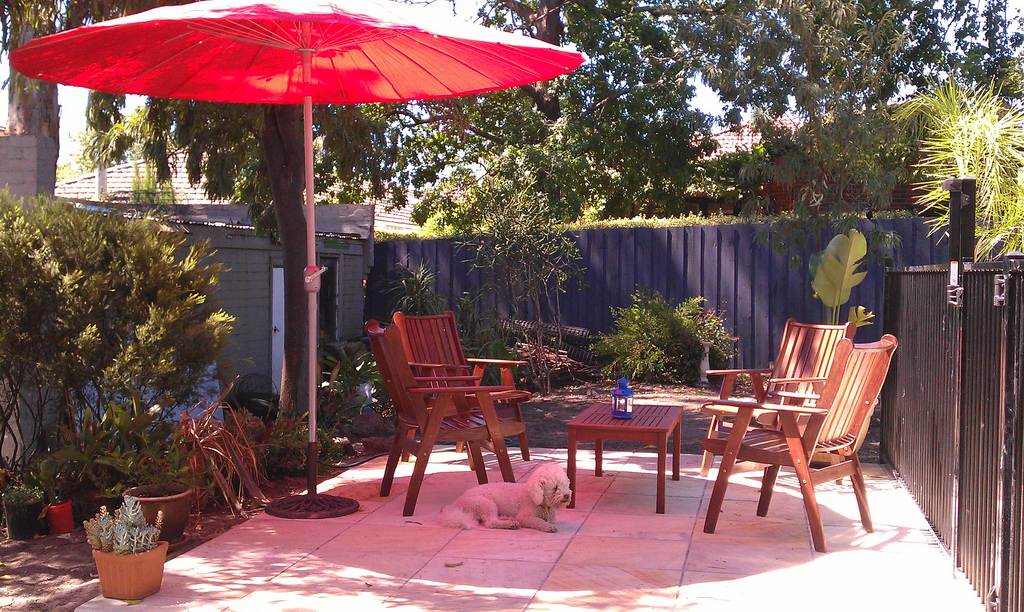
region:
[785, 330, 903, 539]
the chair is brown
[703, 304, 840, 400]
the chair is brown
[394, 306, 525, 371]
the chair is brown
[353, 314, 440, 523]
the chair is brown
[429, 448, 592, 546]
white dog is lying on the floor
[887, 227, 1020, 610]
the fence is color brown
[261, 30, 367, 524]
the shaft is white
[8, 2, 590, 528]
outdoor patio umbrella open on patio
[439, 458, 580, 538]
poodle with puppy cut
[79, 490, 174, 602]
succulent plant in earthenware pot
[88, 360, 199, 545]
potted plant on backyard patio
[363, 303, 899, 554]
set of wooden patio furniture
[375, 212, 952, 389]
black wooden fence bordering yard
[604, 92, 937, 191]
roof of the next door neighbor's house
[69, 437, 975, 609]
tiled patio with marble look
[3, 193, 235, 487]
shrubbery bordering back yard patio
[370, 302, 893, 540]
table and chairs are wood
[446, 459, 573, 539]
dog is laying on the ground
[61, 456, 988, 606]
ground is square bricks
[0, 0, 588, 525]
red umbrella is large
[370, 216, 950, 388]
fence is wooden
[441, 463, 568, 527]
white dog has its head up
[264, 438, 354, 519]
anchor for the umbrella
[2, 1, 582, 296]
umbrella is open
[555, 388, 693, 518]
a table is color brown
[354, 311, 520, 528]
the chair is wod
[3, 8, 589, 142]
the umbrella is open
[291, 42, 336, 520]
shaft holding an umbrella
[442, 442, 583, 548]
the dog is color white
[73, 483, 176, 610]
a pot has plants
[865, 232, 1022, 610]
the fence is color brown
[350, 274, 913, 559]
four chairs around a table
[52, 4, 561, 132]
large open red umbrella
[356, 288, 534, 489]
chair outside on porch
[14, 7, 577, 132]
open red umbrella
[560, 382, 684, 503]
small brown wooden table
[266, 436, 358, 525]
black bottom of umbrella stand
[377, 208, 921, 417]
navy blue yard fence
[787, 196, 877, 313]
large green tree frond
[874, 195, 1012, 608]
black metal fence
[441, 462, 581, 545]
dog next to table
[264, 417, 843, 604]
black umbrella shadow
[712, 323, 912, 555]
empty brown wooden chair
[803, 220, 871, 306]
A leaf on a stem.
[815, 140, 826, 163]
A leaf on a stem.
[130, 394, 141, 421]
A leaf on a stem.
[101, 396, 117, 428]
A leaf on a stem.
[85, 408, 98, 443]
A leaf on a stem.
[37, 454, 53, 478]
A leaf on a stem.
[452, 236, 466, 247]
A leaf on a stem.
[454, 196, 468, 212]
A leaf on a stem.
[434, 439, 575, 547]
dog sitting below umbrella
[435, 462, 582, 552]
shaggy white furry dog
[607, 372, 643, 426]
blue metal lantern on table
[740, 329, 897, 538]
empty brown wooden deck chair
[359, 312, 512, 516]
empty brown wooden deck chair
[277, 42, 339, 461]
white metal umbrella pole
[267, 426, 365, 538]
black plastic umbrella stand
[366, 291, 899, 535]
chairs around a table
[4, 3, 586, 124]
a large red umbrella